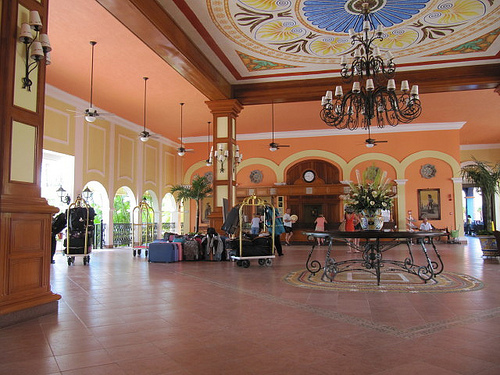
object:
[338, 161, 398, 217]
flowers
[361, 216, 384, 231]
pot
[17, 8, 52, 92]
lighting fixture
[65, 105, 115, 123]
fans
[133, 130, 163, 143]
fans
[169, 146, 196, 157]
fans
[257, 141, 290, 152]
fans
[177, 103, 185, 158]
pendant light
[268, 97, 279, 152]
pendant light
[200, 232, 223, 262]
suitcases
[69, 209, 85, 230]
suitcases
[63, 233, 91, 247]
suitcases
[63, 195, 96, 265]
cart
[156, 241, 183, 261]
suitcases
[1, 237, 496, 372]
floor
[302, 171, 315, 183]
clock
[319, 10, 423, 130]
chandelier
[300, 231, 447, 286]
table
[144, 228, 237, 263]
pile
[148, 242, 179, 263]
luggage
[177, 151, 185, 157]
light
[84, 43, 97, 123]
pendant light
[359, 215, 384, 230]
vase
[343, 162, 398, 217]
plant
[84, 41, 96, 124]
light fixture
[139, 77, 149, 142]
light fixture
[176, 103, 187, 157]
light fixture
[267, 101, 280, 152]
light fixture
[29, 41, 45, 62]
sconce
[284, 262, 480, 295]
design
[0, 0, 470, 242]
wall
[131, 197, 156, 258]
wheeled cart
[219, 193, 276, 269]
cart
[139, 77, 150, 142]
pendant light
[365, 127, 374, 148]
pendant light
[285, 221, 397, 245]
counter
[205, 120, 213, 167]
pendant light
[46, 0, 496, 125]
ceiling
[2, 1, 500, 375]
lobby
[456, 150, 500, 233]
floor plant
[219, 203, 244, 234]
suitcase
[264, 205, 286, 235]
suitcase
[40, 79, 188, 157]
molding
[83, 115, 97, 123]
light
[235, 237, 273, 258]
luggage